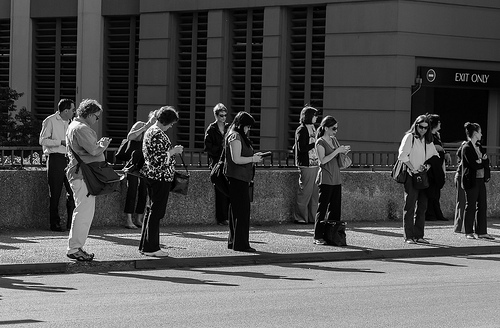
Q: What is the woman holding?
A: A black purse.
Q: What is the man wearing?
A: White pants.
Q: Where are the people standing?
A: On the sidewalk.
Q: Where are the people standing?
A: A city sidewalk.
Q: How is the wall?
A: A short concrete.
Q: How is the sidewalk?
A: Full of people.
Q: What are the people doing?
A: They are standing on the sidewalk.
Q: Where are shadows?
A: On the pavement.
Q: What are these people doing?
A: Checking their phones.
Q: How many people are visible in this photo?
A: Twelve.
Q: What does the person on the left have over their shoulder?
A: A bag.